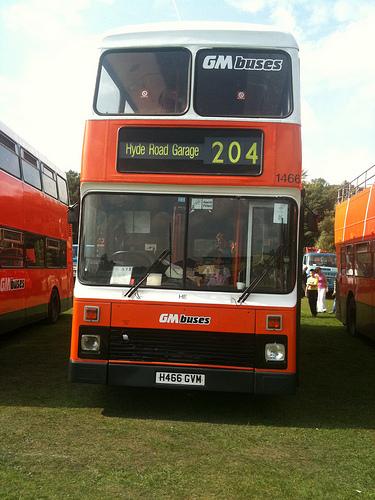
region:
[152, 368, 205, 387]
White license plate in front of the car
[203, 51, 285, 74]
GM buses logo on top right window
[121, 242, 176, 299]
Black windshield on clear window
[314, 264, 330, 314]
Woman wearing white skirt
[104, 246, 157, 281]
Black steering wheel behind window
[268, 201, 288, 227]
White paper taped on window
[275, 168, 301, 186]
Number 1466 on orange middle of bus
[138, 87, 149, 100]
Red and white sticker on window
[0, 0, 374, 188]
Sky is clear and blue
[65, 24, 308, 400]
Bus is double decker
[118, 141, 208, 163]
hyde road garage is where the bus is going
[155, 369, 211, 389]
H466 GVM is the license plate on the bus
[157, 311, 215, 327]
GM buses is written across the front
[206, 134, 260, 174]
The route number is 204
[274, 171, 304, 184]
the bus id is 1466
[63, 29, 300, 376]
the bus is a double decker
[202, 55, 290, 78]
GM buses is also written across the 2nd level window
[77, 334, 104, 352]
the headlight on the front of the bus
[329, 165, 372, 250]
this bus has an open 2nd level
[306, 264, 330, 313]
people standing behind the buses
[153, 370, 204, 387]
small white license plate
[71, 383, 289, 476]
green grass on the ground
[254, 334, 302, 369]
small shiny silver light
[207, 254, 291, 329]
long black wind shield wiper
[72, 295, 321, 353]
red color on front of bus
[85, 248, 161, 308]
white sign in front of bus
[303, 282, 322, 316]
man wearing black pants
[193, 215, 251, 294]
people sitting in bus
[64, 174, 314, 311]
large front window on bus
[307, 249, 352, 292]
blue truck parked at back of bus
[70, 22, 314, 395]
Double decker bus.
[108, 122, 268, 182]
Destination route name and number.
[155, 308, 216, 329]
Manufacturing company of bus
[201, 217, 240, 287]
Bus Driver in driver's seat.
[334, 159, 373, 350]
Open top tourist bus.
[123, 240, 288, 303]
Windshield wipers on front window of bus.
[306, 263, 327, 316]
Two ladies standing beside bus.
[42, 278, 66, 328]
Back tire on bus.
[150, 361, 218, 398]
License number of bus.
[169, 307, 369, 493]
Shadow of bus.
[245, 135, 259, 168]
number on the front of a bus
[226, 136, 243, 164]
number on the front of a bus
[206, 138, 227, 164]
number on the front of a bus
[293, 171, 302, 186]
number on the front of a bus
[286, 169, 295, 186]
number on the front of a bus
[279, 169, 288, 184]
number on the front of a bus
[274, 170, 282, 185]
number on the front of a bus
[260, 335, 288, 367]
headlight on a bus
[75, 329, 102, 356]
headlight on a bus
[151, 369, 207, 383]
white license plate on a bus